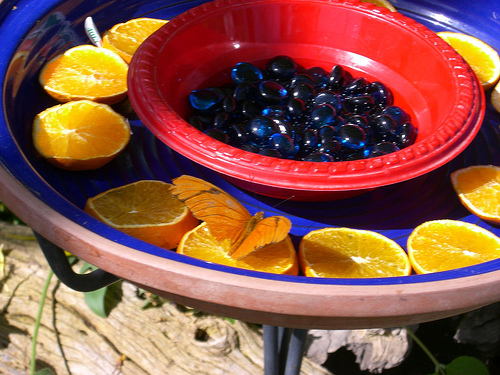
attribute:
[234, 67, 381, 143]
pebbles — blue, glass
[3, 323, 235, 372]
wood — distressed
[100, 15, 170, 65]
orange — half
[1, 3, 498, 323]
platter — brown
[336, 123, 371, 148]
gems — blue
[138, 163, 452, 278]
orange — half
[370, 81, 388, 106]
jewel — blue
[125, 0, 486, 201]
bowl — red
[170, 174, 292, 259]
butterfly — orange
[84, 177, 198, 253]
orange — half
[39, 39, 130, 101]
orange — half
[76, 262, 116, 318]
leaf — green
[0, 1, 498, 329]
bowl — blue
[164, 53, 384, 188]
pebbles — glass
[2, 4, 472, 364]
bowl — blue